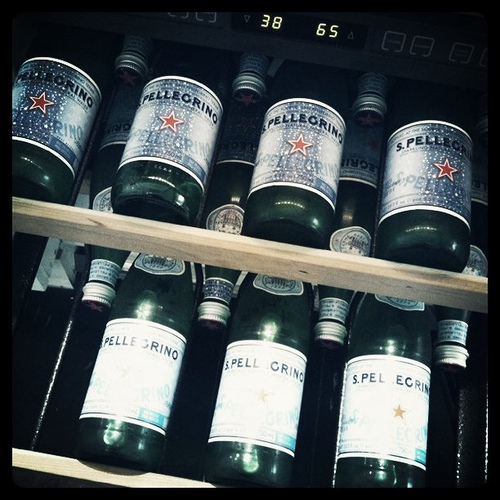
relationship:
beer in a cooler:
[110, 34, 225, 226] [2, 1, 497, 499]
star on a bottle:
[27, 90, 52, 117] [13, 1, 111, 208]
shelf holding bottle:
[12, 198, 489, 314] [13, 1, 111, 208]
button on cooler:
[379, 29, 407, 55] [2, 1, 497, 499]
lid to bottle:
[199, 300, 233, 327] [197, 265, 242, 327]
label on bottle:
[13, 57, 103, 177] [13, 1, 111, 208]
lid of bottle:
[199, 300, 233, 327] [197, 265, 242, 327]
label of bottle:
[13, 57, 103, 177] [13, 1, 111, 208]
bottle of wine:
[13, 1, 111, 208] [10, 5, 106, 205]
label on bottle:
[208, 340, 309, 457] [203, 280, 313, 489]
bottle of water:
[197, 265, 242, 327] [203, 105, 266, 236]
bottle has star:
[197, 265, 242, 327] [162, 111, 183, 131]